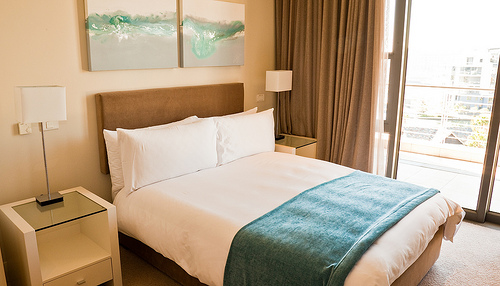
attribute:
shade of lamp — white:
[21, 87, 68, 122]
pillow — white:
[117, 119, 218, 193]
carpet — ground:
[120, 219, 498, 285]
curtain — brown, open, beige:
[275, 1, 385, 173]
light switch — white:
[18, 124, 33, 135]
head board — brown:
[96, 83, 258, 173]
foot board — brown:
[391, 223, 444, 285]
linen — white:
[113, 151, 466, 285]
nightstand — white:
[0, 186, 123, 285]